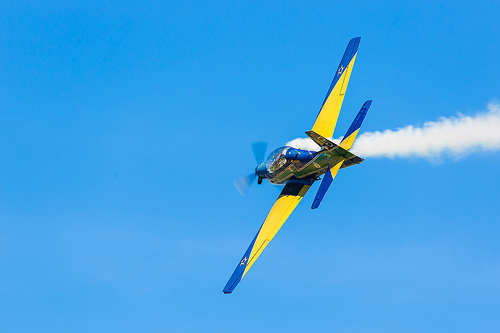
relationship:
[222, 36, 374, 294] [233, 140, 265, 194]
plane has propeller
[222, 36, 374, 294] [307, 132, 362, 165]
plane has tail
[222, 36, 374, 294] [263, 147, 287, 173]
plane has windshield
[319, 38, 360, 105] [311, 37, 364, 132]
blue paint on wing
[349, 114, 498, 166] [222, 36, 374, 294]
smoke trail from plane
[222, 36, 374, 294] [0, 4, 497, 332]
plane in sky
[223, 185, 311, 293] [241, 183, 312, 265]
wing has left side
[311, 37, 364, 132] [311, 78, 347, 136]
wing has right side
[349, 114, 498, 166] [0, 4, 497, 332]
smoke trail in sky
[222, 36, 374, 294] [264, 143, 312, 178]
plane has cockpit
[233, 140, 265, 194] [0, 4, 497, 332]
propeller in sky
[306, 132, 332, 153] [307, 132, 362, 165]
logo on tail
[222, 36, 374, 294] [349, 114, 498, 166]
plane has smoke trail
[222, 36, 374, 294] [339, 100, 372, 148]
plane has tail wing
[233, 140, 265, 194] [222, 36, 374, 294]
propeller on plane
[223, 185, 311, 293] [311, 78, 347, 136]
wing has right side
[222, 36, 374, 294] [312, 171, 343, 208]
plane has hind left wing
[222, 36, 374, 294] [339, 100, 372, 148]
plane has hind right wing